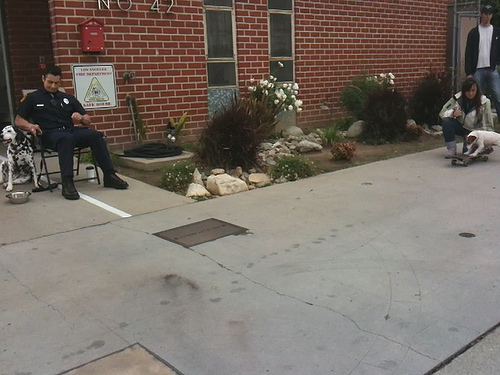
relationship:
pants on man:
[35, 119, 130, 191] [10, 54, 134, 202]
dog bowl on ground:
[8, 182, 33, 210] [311, 183, 438, 300]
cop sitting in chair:
[12, 65, 128, 201] [23, 87, 101, 191]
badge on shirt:
[61, 91, 73, 111] [15, 86, 97, 170]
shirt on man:
[28, 77, 162, 197] [44, 61, 124, 172]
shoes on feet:
[54, 174, 134, 200] [44, 122, 126, 199]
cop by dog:
[1, 30, 213, 350] [1, 115, 42, 199]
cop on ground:
[1, 30, 213, 350] [0, 183, 499, 372]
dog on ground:
[1, 115, 42, 199] [0, 183, 499, 372]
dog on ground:
[459, 125, 487, 158] [0, 183, 499, 372]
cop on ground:
[12, 65, 128, 201] [0, 183, 499, 372]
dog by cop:
[459, 125, 487, 158] [12, 65, 128, 201]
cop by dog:
[12, 65, 128, 201] [1, 115, 42, 199]